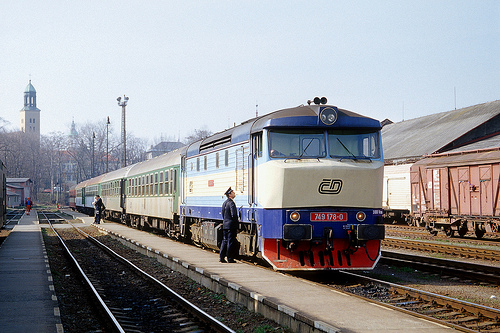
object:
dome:
[24, 84, 36, 94]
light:
[320, 107, 338, 126]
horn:
[307, 97, 321, 106]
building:
[18, 71, 41, 151]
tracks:
[336, 271, 500, 320]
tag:
[309, 211, 348, 222]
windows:
[266, 127, 327, 159]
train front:
[260, 105, 385, 272]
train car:
[408, 146, 500, 240]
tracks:
[380, 248, 500, 275]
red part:
[259, 238, 384, 271]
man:
[218, 185, 239, 263]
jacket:
[221, 198, 240, 230]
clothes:
[219, 197, 240, 259]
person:
[25, 196, 34, 215]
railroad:
[36, 203, 297, 332]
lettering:
[315, 213, 344, 220]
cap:
[222, 185, 234, 195]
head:
[224, 186, 237, 199]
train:
[67, 96, 387, 272]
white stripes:
[249, 291, 267, 302]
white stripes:
[172, 257, 181, 263]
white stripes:
[49, 285, 55, 291]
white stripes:
[118, 234, 121, 237]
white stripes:
[277, 304, 299, 318]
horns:
[321, 96, 328, 104]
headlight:
[289, 211, 300, 222]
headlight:
[356, 211, 367, 222]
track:
[38, 206, 123, 333]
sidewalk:
[0, 205, 65, 333]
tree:
[61, 116, 148, 184]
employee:
[93, 194, 103, 225]